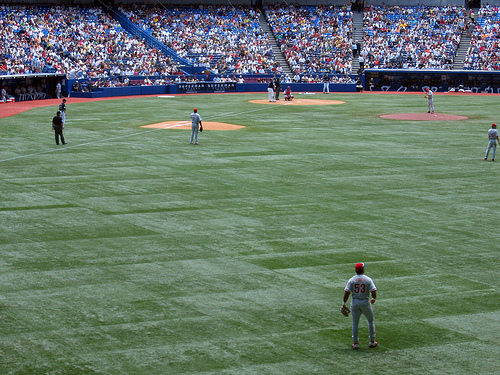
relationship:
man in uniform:
[338, 258, 380, 349] [331, 263, 402, 370]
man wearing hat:
[338, 258, 380, 349] [331, 260, 391, 290]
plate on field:
[257, 86, 347, 129] [175, 212, 314, 276]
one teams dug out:
[3, 61, 71, 120] [25, 99, 37, 136]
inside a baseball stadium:
[4, 64, 498, 375] [90, 110, 304, 282]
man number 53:
[338, 258, 380, 349] [350, 289, 370, 308]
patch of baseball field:
[74, 203, 179, 323] [5, 171, 470, 375]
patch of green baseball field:
[146, 198, 257, 318] [77, 130, 387, 321]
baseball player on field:
[329, 239, 399, 375] [272, 209, 497, 375]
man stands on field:
[338, 258, 380, 349] [0, 86, 498, 372]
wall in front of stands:
[64, 81, 364, 96] [63, 71, 363, 97]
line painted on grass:
[0, 100, 297, 162] [0, 91, 484, 371]